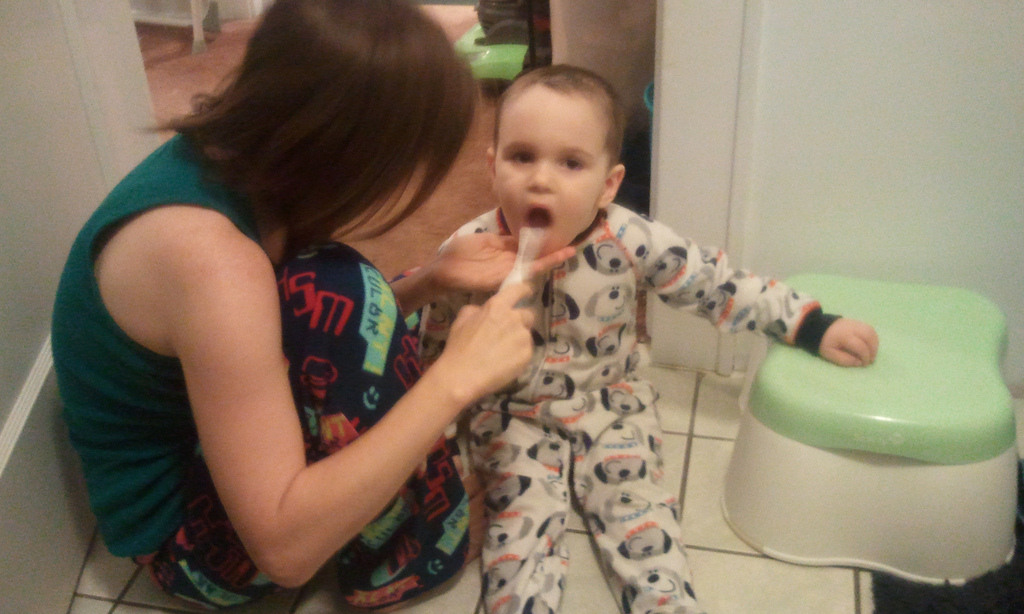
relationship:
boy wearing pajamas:
[455, 59, 851, 610] [445, 206, 703, 608]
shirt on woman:
[55, 136, 254, 551] [50, 1, 573, 609]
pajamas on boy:
[440, 201, 838, 606] [399, 59, 884, 614]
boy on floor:
[399, 59, 884, 614] [73, 357, 992, 608]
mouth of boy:
[521, 203, 556, 232] [399, 59, 884, 614]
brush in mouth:
[498, 223, 548, 288] [521, 203, 556, 232]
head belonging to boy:
[485, 61, 626, 262] [399, 59, 884, 614]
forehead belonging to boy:
[491, 85, 606, 153] [399, 59, 884, 614]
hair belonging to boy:
[487, 61, 626, 168] [399, 59, 884, 614]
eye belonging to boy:
[508, 147, 537, 165] [399, 59, 884, 614]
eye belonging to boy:
[556, 150, 587, 170] [399, 59, 884, 614]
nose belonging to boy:
[521, 156, 558, 195] [399, 59, 884, 614]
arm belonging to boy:
[634, 215, 881, 371] [399, 59, 884, 614]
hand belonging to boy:
[815, 309, 882, 370] [399, 59, 884, 614]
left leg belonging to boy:
[569, 400, 704, 610] [399, 59, 884, 614]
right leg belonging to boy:
[472, 404, 568, 610] [399, 59, 884, 614]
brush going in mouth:
[497, 223, 545, 288] [513, 197, 555, 245]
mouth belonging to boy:
[513, 197, 555, 245] [399, 59, 884, 614]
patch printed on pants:
[357, 258, 399, 379] [139, 236, 472, 608]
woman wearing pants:
[50, 1, 573, 609] [139, 236, 472, 608]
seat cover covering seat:
[746, 266, 993, 470] [716, 273, 993, 582]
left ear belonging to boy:
[593, 163, 624, 211] [399, 59, 884, 614]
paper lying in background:
[454, 24, 532, 85] [128, 3, 656, 276]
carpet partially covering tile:
[871, 452, 993, 606] [70, 338, 878, 609]